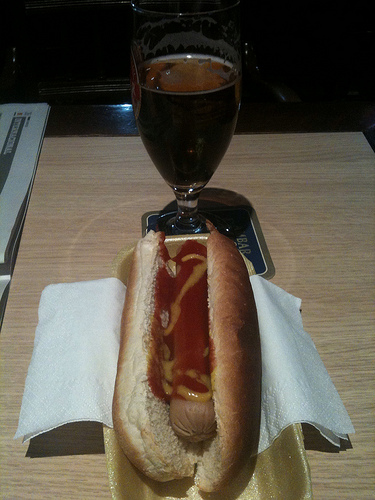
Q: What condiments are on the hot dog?
A: Ketchup and mustard.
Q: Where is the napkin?
A: Under the hot dog.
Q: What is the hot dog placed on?
A: A yellow tray.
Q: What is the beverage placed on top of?
A: On a coaster.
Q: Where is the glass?
A: Above the hot dog.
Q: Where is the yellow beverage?
A: In the tall glass.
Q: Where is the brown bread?
A: Around the hotdog.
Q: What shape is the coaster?
A: Square.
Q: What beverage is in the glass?
A: Beer.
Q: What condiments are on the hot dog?
A: Mustard and ketchup.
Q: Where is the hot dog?
A: On the table.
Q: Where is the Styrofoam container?
A: On the table under the hot dog and napkin.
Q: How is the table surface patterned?
A: With a wood grain.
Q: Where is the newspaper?
A: To the left of the beer on the table.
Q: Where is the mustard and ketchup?
A: On the hot dog.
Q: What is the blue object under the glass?
A: A coaster.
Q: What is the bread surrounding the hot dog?
A: A hot dog bun.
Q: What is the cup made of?
A: Glass.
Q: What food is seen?
A: Hot dog.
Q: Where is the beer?
A: Behind the hot dog.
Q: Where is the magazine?
A: On the left.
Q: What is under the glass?
A: A coaster.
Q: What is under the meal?
A: A table.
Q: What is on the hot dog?
A: Ketchup and mustard.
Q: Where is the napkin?
A: Under the food.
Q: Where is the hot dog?
A: In a bun.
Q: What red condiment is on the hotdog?
A: Ketchup.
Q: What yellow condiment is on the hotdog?
A: Mustard.